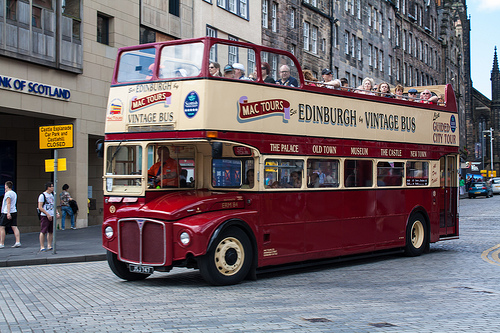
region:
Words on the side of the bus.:
[297, 93, 424, 139]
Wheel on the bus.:
[196, 217, 271, 284]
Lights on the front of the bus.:
[87, 203, 188, 265]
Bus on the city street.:
[56, 29, 488, 312]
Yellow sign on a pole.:
[37, 120, 84, 187]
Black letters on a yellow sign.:
[34, 118, 79, 159]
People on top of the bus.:
[277, 50, 487, 114]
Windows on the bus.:
[257, 151, 452, 189]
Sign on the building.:
[5, 55, 75, 103]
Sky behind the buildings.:
[470, 12, 492, 94]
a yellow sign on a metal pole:
[49, 120, 71, 261]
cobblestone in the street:
[119, 303, 183, 325]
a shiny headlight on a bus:
[167, 217, 194, 252]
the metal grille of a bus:
[113, 216, 173, 270]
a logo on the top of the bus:
[239, 89, 300, 131]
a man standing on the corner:
[38, 180, 57, 252]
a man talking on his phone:
[3, 174, 23, 249]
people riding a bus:
[247, 60, 424, 101]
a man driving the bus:
[149, 144, 179, 191]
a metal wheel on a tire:
[209, 232, 253, 277]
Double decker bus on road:
[77, 36, 477, 331]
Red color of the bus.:
[87, 146, 416, 265]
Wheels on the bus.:
[196, 210, 280, 281]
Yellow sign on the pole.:
[25, 97, 120, 204]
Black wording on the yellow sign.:
[29, 105, 119, 181]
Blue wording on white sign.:
[12, 75, 83, 109]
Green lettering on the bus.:
[280, 88, 431, 140]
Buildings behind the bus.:
[312, 6, 492, 57]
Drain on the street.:
[237, 297, 350, 329]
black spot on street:
[280, 305, 360, 325]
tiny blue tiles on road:
[64, 277, 142, 322]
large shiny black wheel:
[195, 237, 274, 297]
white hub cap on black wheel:
[215, 235, 247, 271]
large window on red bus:
[259, 147, 316, 198]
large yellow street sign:
[26, 108, 87, 164]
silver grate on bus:
[98, 210, 171, 277]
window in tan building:
[89, 10, 128, 51]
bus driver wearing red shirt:
[125, 136, 199, 208]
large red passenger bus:
[83, 22, 497, 235]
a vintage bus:
[93, 34, 483, 289]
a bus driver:
[122, 138, 195, 196]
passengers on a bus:
[115, 56, 450, 107]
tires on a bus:
[190, 212, 269, 295]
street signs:
[27, 115, 77, 181]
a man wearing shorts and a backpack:
[31, 180, 56, 255]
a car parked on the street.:
[464, 178, 496, 201]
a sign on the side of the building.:
[0, 72, 73, 103]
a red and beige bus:
[90, 32, 477, 288]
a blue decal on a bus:
[179, 83, 201, 124]